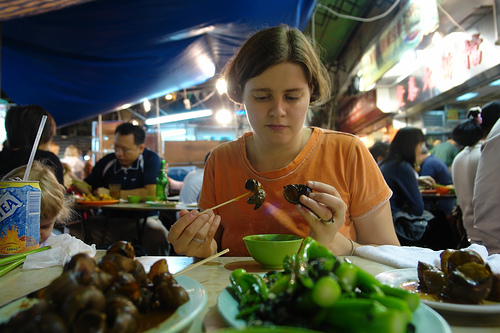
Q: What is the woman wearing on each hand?
A: A ring.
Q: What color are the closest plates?
A: White.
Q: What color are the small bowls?
A: Green.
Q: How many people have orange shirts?
A: One.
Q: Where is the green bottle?
A: On the table to the left.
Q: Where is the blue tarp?
A: On the ceiling.